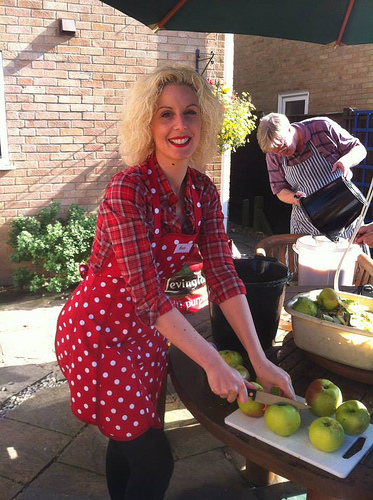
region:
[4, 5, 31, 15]
red brick on building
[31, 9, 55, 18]
red brick on building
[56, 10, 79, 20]
red brick on building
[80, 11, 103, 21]
red brick on building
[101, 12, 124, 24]
red brick on building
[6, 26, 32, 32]
red brick on building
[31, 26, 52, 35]
red brick on building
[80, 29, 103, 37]
red brick on building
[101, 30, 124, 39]
red brick on building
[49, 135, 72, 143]
red brick on building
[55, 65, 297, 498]
a woman wearing a red polka dot apron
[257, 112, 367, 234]
a man wearing a striped apron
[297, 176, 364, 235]
a black plastic bucket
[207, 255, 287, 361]
a large black plastic trash can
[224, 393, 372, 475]
a white cutting board on the table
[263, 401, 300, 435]
a green apple on a cutting board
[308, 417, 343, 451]
a green apple on a cutting board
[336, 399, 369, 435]
a green apple on a cutting board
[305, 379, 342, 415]
a green apple on a cutting board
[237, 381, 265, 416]
a green apple on a cutting board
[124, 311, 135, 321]
polka dot on the apron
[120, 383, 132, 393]
polka dot on the apron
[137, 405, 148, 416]
polka dot on the apron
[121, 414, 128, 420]
polka dot on the apron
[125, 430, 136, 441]
polka dot on the apron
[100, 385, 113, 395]
polka dot on the apron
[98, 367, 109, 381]
polka dot on the apron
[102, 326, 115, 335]
polka dot on the apron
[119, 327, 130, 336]
polka dot on the apron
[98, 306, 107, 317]
polka dot on the apron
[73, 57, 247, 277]
the woman is blonde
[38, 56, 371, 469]
woman cutting apples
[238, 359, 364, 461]
apples are green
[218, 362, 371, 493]
apples are on a white board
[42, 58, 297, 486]
woman has an apron on front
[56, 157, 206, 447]
the apron is red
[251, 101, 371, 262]
man holding a black bucket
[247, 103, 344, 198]
the man is blonde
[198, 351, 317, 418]
hand holding a knife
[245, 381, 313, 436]
blade in a apple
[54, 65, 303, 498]
Blonde woman cutting green apples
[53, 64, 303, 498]
Woman wearing red and white polka-dotted apron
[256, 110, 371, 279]
Man pouring something from black bucket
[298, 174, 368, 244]
Small black bucket held by man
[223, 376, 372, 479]
Green apples on white cutting board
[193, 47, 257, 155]
Yellow-flowered plant hanging from plant bracket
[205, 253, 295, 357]
Small black bucket sitting on table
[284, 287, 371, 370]
White tub holding apples and apple pieces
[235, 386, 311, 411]
Large knife being used to cut apples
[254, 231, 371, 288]
Brown wooden chair holding white bucket